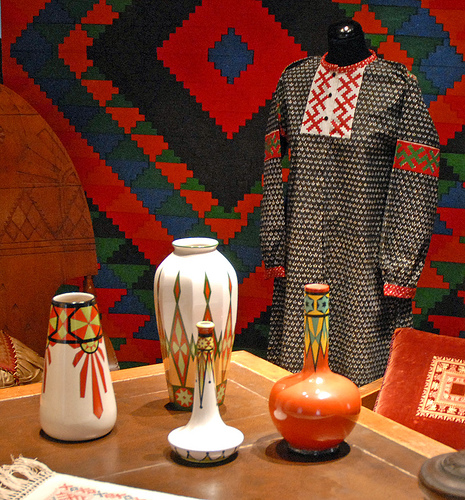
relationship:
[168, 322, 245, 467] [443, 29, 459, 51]
artifact from america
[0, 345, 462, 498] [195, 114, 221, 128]
table with trim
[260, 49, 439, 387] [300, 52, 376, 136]
suit has design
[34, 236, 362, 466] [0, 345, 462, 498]
bottles on table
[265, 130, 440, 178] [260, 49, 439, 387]
design on suit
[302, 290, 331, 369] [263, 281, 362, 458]
design on bottles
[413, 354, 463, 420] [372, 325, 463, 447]
design on pillow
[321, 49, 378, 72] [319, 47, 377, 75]
symbols on collar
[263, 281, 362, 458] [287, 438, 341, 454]
bottles with base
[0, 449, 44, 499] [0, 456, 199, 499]
fringe on cloth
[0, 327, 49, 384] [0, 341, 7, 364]
rug has design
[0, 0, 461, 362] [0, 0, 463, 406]
design on wall